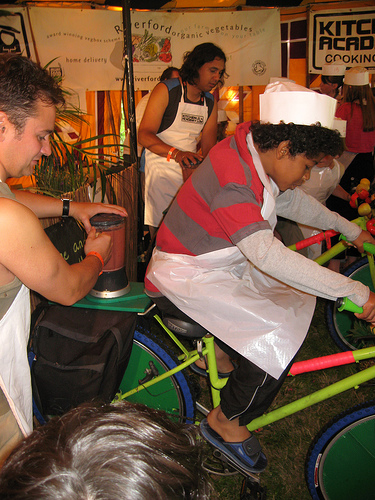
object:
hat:
[259, 75, 336, 131]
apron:
[1, 255, 34, 437]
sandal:
[200, 416, 268, 475]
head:
[3, 407, 204, 500]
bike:
[92, 211, 375, 496]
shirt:
[146, 120, 274, 287]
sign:
[308, 8, 374, 73]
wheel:
[296, 407, 375, 499]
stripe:
[228, 380, 271, 422]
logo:
[181, 111, 204, 125]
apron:
[144, 79, 209, 225]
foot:
[193, 397, 271, 476]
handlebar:
[336, 299, 372, 325]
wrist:
[86, 250, 104, 276]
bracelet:
[86, 252, 104, 276]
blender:
[83, 213, 131, 299]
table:
[60, 272, 155, 313]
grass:
[168, 356, 373, 500]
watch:
[59, 197, 78, 216]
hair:
[251, 121, 343, 154]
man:
[0, 56, 129, 470]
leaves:
[31, 70, 136, 203]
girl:
[146, 76, 374, 481]